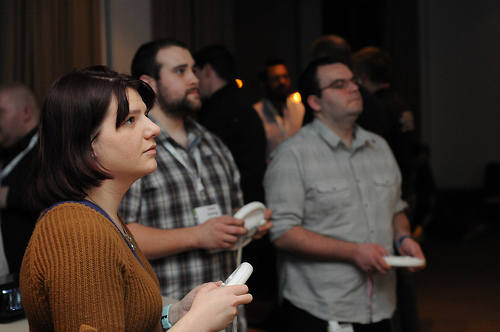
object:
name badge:
[192, 202, 229, 254]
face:
[318, 62, 363, 112]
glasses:
[321, 77, 357, 91]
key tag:
[193, 203, 227, 254]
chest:
[139, 144, 234, 226]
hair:
[297, 60, 342, 113]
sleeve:
[263, 146, 306, 242]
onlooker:
[252, 62, 307, 164]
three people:
[18, 39, 426, 332]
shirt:
[263, 117, 408, 325]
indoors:
[0, 0, 500, 332]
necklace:
[81, 189, 137, 251]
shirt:
[118, 115, 243, 332]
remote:
[227, 200, 268, 251]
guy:
[262, 58, 427, 332]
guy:
[116, 39, 274, 332]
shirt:
[18, 202, 163, 332]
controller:
[377, 254, 426, 268]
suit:
[200, 83, 281, 330]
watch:
[160, 303, 173, 330]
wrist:
[180, 225, 201, 253]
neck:
[79, 177, 139, 214]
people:
[18, 65, 254, 332]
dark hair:
[22, 68, 158, 213]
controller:
[219, 262, 254, 289]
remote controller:
[218, 262, 254, 289]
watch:
[396, 235, 412, 251]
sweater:
[19, 201, 164, 332]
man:
[0, 83, 42, 332]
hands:
[179, 280, 254, 331]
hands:
[197, 208, 274, 250]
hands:
[353, 238, 426, 275]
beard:
[157, 86, 202, 116]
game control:
[227, 201, 268, 252]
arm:
[262, 150, 338, 263]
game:
[176, 138, 499, 332]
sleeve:
[43, 205, 129, 332]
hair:
[130, 38, 188, 81]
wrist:
[395, 232, 411, 242]